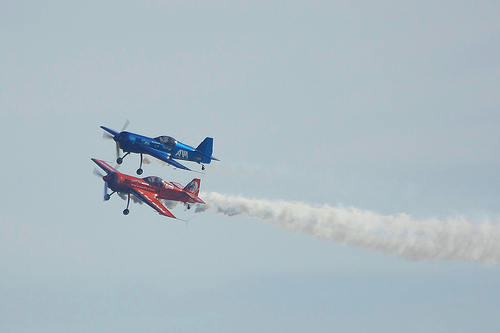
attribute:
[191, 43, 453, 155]
sky — gray, blue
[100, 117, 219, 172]
airplane — blue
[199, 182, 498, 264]
smoke — grey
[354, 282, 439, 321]
sky — section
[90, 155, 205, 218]
plane — red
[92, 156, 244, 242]
plane — red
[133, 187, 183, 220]
wing — red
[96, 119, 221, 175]
plane — blue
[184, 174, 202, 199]
tail fin — red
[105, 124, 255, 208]
plane — blue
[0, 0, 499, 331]
sky — blue, Section 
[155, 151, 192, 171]
wing — blue